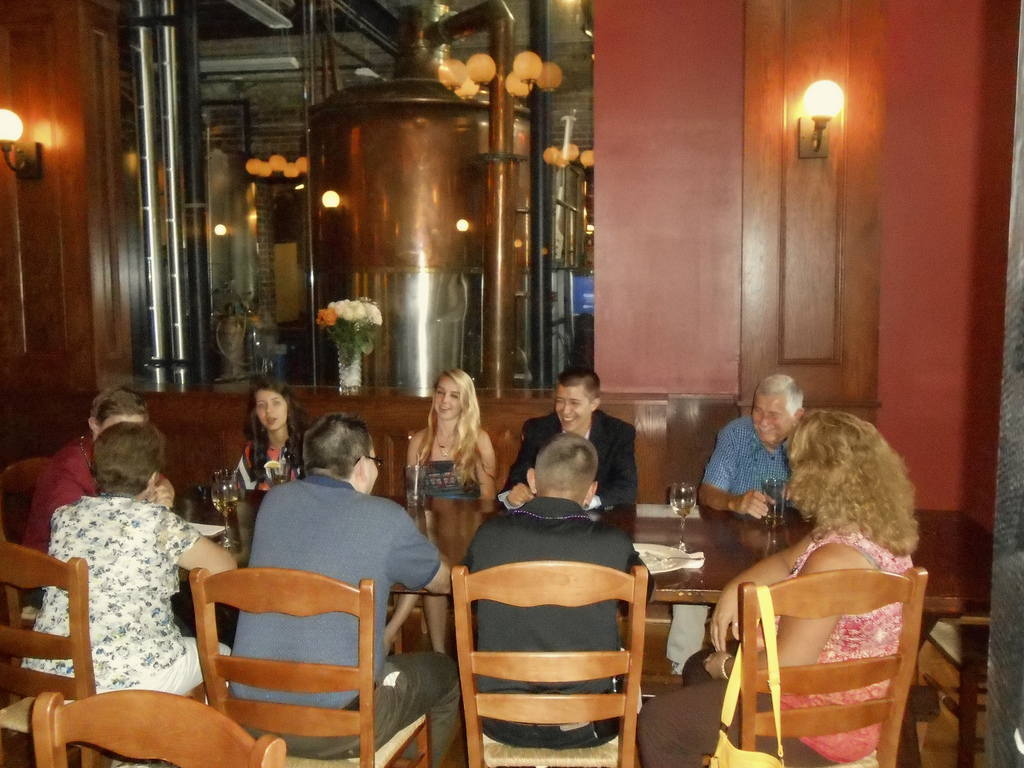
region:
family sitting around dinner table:
[2, 369, 933, 765]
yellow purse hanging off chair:
[700, 565, 929, 765]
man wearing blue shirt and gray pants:
[222, 410, 464, 766]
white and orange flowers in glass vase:
[311, 293, 382, 395]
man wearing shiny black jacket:
[443, 421, 653, 750]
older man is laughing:
[691, 368, 815, 518]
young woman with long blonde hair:
[402, 366, 498, 509]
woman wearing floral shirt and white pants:
[19, 417, 241, 766]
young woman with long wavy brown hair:
[228, 376, 311, 494]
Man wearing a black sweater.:
[459, 430, 653, 753]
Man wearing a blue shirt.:
[225, 410, 459, 766]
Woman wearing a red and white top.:
[637, 407, 928, 766]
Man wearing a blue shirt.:
[700, 372, 815, 521]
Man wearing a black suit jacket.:
[494, 366, 641, 515]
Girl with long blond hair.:
[399, 370, 501, 504]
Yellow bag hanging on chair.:
[697, 576, 803, 766]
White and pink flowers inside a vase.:
[310, 293, 386, 398]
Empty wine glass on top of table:
[667, 478, 700, 554]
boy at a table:
[464, 443, 635, 764]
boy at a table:
[249, 418, 446, 761]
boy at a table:
[520, 374, 635, 507]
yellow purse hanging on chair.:
[689, 576, 811, 764]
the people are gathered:
[65, 93, 916, 679]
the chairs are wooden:
[435, 535, 657, 739]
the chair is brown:
[425, 512, 692, 732]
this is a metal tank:
[282, 79, 586, 333]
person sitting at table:
[449, 433, 636, 753]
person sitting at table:
[699, 411, 916, 757]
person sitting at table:
[692, 357, 813, 529]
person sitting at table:
[499, 364, 645, 516]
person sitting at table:
[403, 363, 498, 503]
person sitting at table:
[231, 380, 312, 486]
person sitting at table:
[16, 369, 173, 547]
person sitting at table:
[29, 414, 246, 710]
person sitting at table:
[223, 417, 462, 763]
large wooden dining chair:
[433, 552, 653, 762]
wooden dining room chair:
[739, 565, 929, 762]